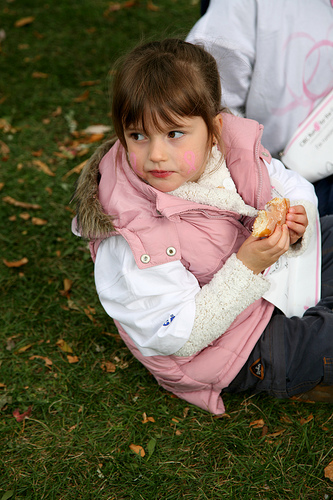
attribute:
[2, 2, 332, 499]
grass — green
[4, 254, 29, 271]
leaf — brown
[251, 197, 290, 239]
donut — partially eaten, glazed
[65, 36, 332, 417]
girl — sitting, little, eating, holding donut, rosy cheeked, small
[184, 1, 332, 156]
shirt — white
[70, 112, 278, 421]
vest — pink, hooded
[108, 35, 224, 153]
hair — brown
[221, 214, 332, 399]
pants — gray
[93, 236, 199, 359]
sleeve — short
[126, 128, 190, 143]
eyes — brown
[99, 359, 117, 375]
leaf — brown